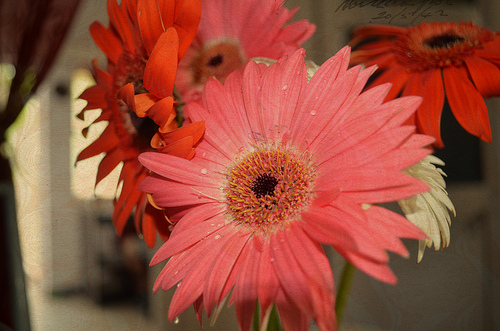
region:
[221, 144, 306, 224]
the orange and black center of a flower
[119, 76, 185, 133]
the orange and black center of a flower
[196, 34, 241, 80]
the orange and black center of a flower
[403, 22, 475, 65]
the orange and black center of a flower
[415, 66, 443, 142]
the red petal of a flower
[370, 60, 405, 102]
the red petal of a flower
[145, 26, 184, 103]
the red petal of a flower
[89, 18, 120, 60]
the red petal of a flower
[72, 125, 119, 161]
the red petal of a flower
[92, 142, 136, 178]
the red petal of a flower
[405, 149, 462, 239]
a large and beautiful white flower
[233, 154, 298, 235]
the center of a pink flower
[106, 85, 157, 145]
the center of a red flower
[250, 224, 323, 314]
the petal of a pink flower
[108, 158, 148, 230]
the petal of a red flower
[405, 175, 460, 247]
the petal of a white flower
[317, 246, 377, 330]
the green stem of a flower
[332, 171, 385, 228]
specks on pollen on a flower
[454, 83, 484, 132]
Red petal on flower.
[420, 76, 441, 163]
Red petal on flower.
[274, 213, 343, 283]
this is a pink petal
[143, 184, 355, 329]
these are pink petals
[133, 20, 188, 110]
this is a red petal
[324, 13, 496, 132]
this is a red flower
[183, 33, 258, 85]
these are the pollups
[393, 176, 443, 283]
this is a white petal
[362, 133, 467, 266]
these are white petals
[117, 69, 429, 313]
this is a pink flower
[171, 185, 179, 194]
this is the color pink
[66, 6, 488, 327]
a group of flowers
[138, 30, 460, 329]
white flower behind the pink one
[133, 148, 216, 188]
narrow pink petal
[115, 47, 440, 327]
pink petals around the flower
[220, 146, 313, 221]
pollen in the middle of the flower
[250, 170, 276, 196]
small dark circle at the center of the flower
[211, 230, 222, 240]
white speck on the petal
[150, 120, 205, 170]
orange petals mixing in with the pink ones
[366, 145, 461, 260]
white petals on the flower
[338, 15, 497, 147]
orange flower